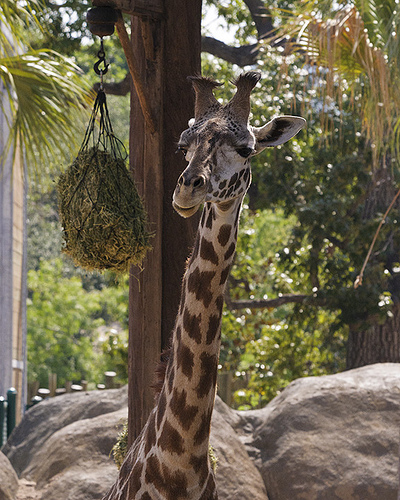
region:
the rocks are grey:
[299, 382, 399, 467]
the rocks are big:
[31, 390, 399, 499]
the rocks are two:
[29, 390, 398, 498]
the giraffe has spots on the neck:
[150, 305, 215, 498]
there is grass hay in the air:
[56, 163, 149, 243]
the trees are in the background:
[308, 150, 382, 251]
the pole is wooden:
[126, 361, 160, 413]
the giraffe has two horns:
[182, 74, 264, 119]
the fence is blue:
[3, 389, 20, 430]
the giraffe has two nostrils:
[172, 171, 209, 220]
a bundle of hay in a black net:
[52, 77, 157, 273]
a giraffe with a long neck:
[91, 69, 311, 498]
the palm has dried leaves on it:
[249, 2, 398, 179]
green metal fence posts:
[0, 384, 24, 441]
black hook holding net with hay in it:
[89, 40, 110, 100]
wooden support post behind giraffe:
[82, 0, 207, 460]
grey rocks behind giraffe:
[1, 360, 397, 497]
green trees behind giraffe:
[28, 0, 397, 408]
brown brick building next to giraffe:
[0, 61, 28, 446]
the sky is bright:
[0, 0, 399, 126]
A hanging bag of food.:
[51, 128, 153, 284]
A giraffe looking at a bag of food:
[123, 86, 265, 495]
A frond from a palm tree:
[2, 80, 79, 173]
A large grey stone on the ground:
[248, 366, 398, 496]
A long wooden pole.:
[127, 11, 195, 420]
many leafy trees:
[272, 152, 396, 318]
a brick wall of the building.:
[2, 153, 30, 404]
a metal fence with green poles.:
[0, 384, 15, 444]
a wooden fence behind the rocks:
[29, 367, 123, 399]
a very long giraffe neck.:
[164, 223, 239, 473]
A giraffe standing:
[104, 56, 308, 496]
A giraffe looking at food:
[96, 68, 304, 496]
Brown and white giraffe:
[100, 65, 320, 497]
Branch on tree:
[228, 292, 324, 308]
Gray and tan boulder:
[257, 357, 397, 493]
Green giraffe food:
[52, 0, 164, 288]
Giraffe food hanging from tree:
[52, 0, 152, 288]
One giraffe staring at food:
[100, 64, 312, 496]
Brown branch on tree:
[224, 284, 328, 308]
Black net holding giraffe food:
[53, 89, 161, 289]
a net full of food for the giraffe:
[56, 130, 146, 277]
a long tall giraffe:
[83, 73, 299, 498]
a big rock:
[12, 393, 237, 498]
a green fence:
[0, 384, 20, 442]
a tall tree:
[345, 265, 396, 369]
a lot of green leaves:
[36, 266, 130, 374]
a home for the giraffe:
[7, 94, 49, 424]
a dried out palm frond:
[276, 4, 397, 138]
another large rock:
[254, 360, 390, 497]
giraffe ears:
[183, 66, 271, 111]